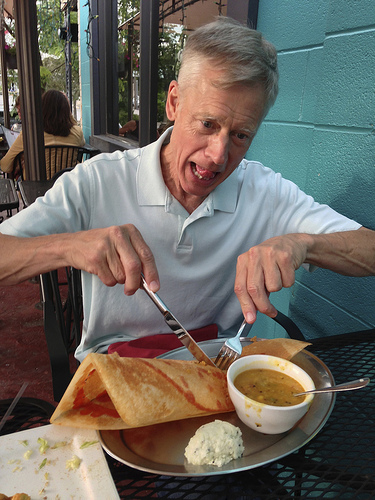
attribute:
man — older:
[10, 24, 374, 438]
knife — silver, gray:
[136, 272, 230, 373]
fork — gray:
[210, 316, 260, 366]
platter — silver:
[89, 330, 332, 476]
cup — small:
[226, 352, 312, 430]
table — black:
[2, 336, 374, 498]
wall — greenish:
[210, 4, 361, 324]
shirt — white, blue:
[6, 126, 354, 370]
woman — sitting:
[8, 93, 75, 190]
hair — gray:
[181, 17, 278, 107]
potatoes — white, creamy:
[185, 421, 241, 464]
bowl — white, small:
[227, 356, 315, 429]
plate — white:
[1, 415, 116, 499]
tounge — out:
[197, 163, 218, 175]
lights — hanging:
[79, 4, 139, 130]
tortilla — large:
[56, 335, 310, 426]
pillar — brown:
[10, 2, 56, 195]